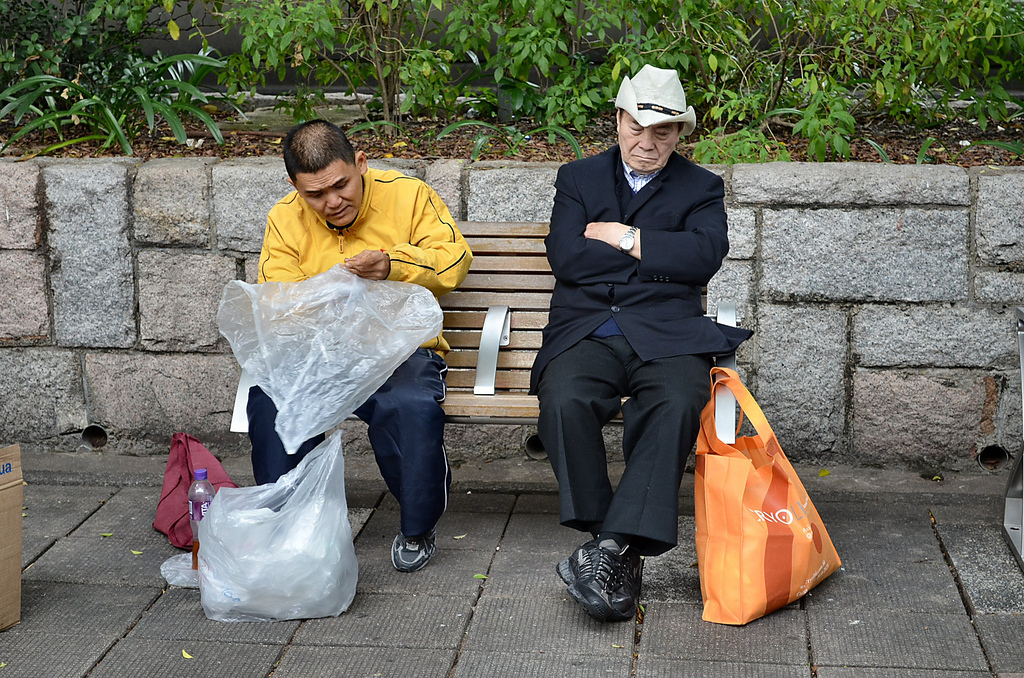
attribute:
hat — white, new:
[605, 55, 698, 138]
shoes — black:
[382, 513, 440, 579]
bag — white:
[202, 255, 443, 446]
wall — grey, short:
[8, 150, 993, 494]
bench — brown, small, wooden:
[234, 214, 722, 442]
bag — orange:
[694, 364, 850, 622]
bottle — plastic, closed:
[178, 459, 217, 555]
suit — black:
[531, 148, 722, 540]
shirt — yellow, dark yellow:
[239, 181, 467, 357]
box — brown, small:
[0, 440, 59, 627]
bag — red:
[126, 430, 237, 555]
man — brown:
[215, 103, 482, 556]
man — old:
[532, 48, 756, 626]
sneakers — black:
[545, 535, 650, 638]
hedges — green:
[4, 4, 1023, 166]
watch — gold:
[618, 224, 641, 258]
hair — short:
[271, 123, 369, 183]